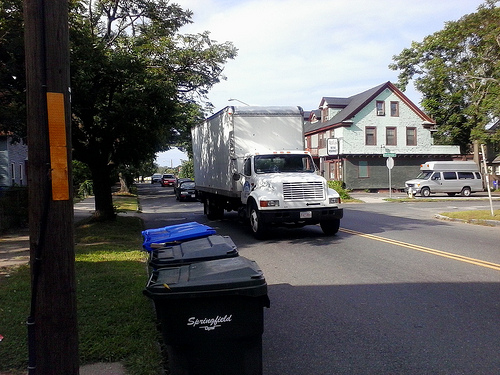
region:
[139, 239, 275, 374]
Black trash cans on side of street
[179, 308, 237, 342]
White letters on black trash cans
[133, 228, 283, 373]
Trash cans are closed with lids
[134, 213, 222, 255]
Blue trash can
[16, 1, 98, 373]
Pole close to trash cans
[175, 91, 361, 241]
White truck on the road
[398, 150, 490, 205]
Grey van on side street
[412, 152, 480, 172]
Big container box on top of van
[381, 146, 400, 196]
Street sign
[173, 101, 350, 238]
white box truck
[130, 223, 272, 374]
trash cans with lids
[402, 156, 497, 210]
silver van in parking lot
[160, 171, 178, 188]
red mini van on street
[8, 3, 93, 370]
telephone pole on side of street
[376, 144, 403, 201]
green street sign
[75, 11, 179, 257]
tree with green leaves on side of street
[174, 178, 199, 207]
black compact car coming down street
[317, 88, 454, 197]
white house with brown trim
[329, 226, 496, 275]
yellow double line in center of street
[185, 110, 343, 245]
A large white truck is in the street.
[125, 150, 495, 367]
The street has two lanes.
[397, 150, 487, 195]
A silver van is parked.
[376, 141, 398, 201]
A street sign.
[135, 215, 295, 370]
Three garbage cans on the side of the road.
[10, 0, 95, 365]
A utility pole.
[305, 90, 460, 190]
A two story building.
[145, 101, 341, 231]
A line of cars are behind the truck.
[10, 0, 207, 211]
A large tree.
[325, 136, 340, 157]
A business sign.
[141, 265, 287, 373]
Black trash can on street curb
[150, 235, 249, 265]
Black trash can on street curb with lid closed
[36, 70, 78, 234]
Gold flag on brown telephone pole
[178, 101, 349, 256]
Large white truck moving on street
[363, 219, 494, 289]
Yellow lines in middle of street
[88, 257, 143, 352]
Green grass on sidewalk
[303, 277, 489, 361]
Gray shadow on street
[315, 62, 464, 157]
Red, white and gray house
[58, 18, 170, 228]
Large green tree on sidewalk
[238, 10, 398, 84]
White clouds in the blue sky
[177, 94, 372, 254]
truck on a street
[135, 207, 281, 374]
trash containers on a street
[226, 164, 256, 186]
side rear view mirror on a vehicle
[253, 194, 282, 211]
front headlight on a vehicle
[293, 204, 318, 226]
front licence plate on a vehicle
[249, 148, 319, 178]
front windshield on a vehicle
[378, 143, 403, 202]
street sign on a pole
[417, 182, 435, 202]
front wheel on a vehicle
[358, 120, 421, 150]
windows on a building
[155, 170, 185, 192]
red vehicle on a street